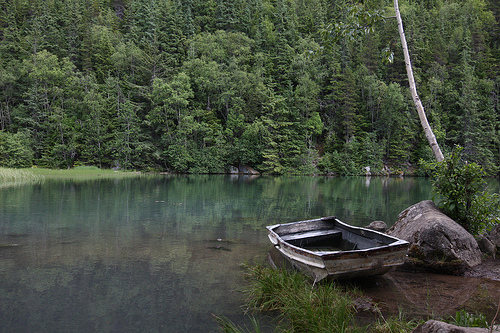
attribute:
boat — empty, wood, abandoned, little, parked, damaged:
[266, 213, 411, 284]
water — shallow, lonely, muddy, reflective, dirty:
[0, 168, 499, 330]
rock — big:
[394, 200, 486, 277]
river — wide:
[0, 165, 497, 332]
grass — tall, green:
[238, 259, 371, 331]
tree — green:
[329, 63, 361, 169]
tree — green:
[253, 85, 301, 176]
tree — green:
[143, 75, 182, 175]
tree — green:
[31, 52, 83, 171]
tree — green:
[450, 38, 500, 178]